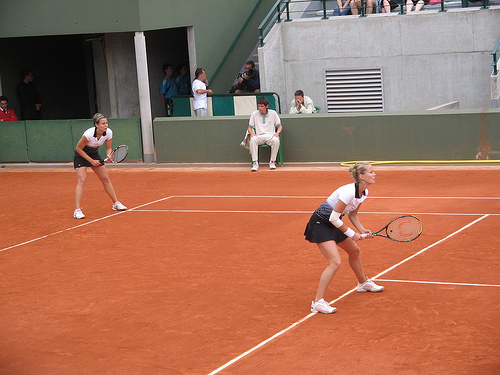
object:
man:
[176, 66, 191, 95]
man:
[160, 63, 178, 116]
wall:
[0, 0, 262, 117]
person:
[303, 162, 384, 314]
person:
[73, 113, 127, 219]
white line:
[374, 279, 499, 287]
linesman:
[248, 96, 283, 172]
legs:
[332, 0, 425, 15]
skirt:
[73, 145, 104, 170]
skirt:
[304, 206, 349, 244]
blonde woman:
[303, 162, 374, 315]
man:
[289, 90, 316, 116]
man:
[234, 60, 260, 93]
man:
[191, 68, 213, 117]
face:
[364, 163, 377, 183]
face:
[98, 118, 108, 132]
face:
[295, 95, 303, 100]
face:
[258, 104, 266, 113]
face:
[245, 64, 253, 75]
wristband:
[344, 227, 356, 238]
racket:
[99, 145, 128, 164]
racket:
[361, 215, 423, 243]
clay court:
[2, 163, 499, 374]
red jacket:
[0, 108, 18, 122]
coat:
[0, 107, 17, 121]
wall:
[0, 117, 143, 164]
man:
[0, 96, 18, 122]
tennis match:
[0, 111, 499, 374]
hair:
[348, 162, 370, 182]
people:
[336, 0, 444, 17]